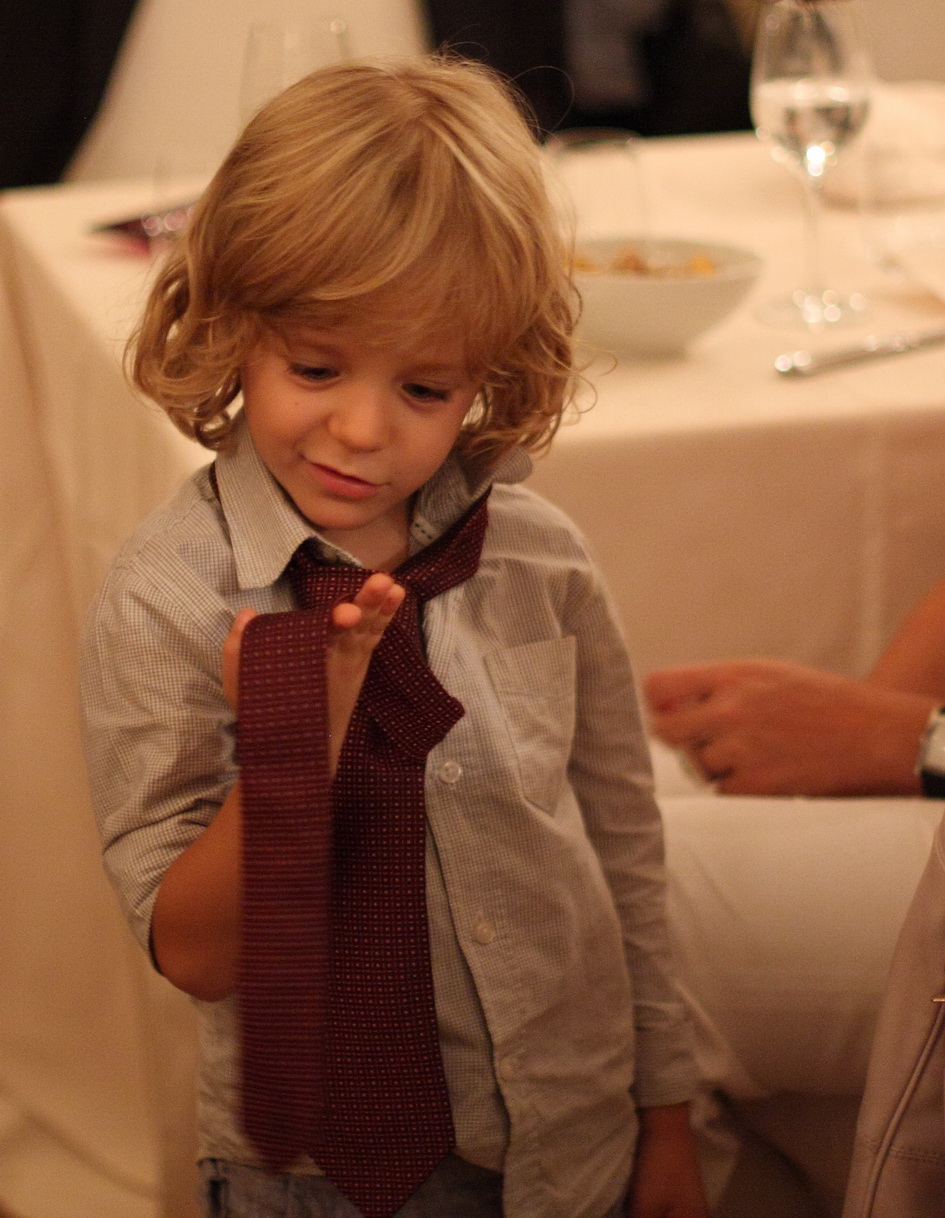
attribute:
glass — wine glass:
[728, 16, 863, 439]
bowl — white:
[571, 206, 808, 473]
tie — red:
[203, 467, 510, 1210]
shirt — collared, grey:
[88, 408, 744, 1210]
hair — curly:
[134, 41, 573, 461]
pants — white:
[620, 730, 906, 1104]